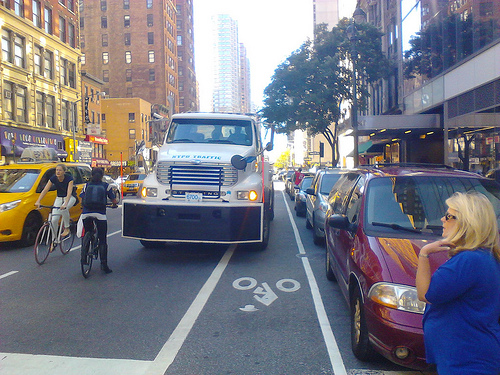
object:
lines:
[281, 183, 345, 375]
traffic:
[1, 110, 268, 245]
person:
[292, 161, 305, 186]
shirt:
[294, 171, 304, 185]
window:
[34, 45, 42, 74]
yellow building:
[1, 6, 84, 138]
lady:
[416, 190, 500, 374]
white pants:
[51, 195, 76, 242]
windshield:
[168, 118, 251, 144]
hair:
[440, 191, 500, 256]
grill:
[155, 161, 237, 186]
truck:
[121, 112, 275, 250]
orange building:
[101, 97, 153, 162]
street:
[0, 168, 497, 375]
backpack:
[83, 182, 106, 209]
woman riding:
[34, 163, 77, 265]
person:
[76, 167, 119, 274]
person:
[35, 164, 77, 253]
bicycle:
[80, 217, 100, 279]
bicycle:
[34, 205, 77, 265]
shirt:
[421, 246, 498, 375]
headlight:
[249, 190, 258, 201]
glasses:
[446, 212, 460, 221]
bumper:
[121, 199, 265, 243]